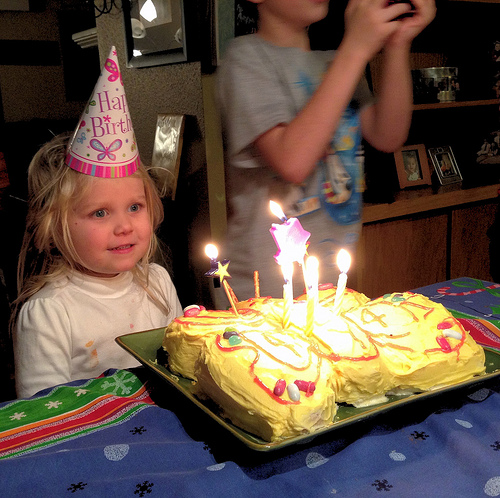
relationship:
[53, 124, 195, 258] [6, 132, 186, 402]
head of child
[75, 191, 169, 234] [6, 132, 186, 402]
eye of child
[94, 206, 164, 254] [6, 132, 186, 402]
nose of child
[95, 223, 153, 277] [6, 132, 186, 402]
mouth of child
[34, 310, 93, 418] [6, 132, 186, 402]
arm of child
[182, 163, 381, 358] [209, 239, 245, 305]
candle with star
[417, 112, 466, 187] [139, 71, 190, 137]
frame on wall